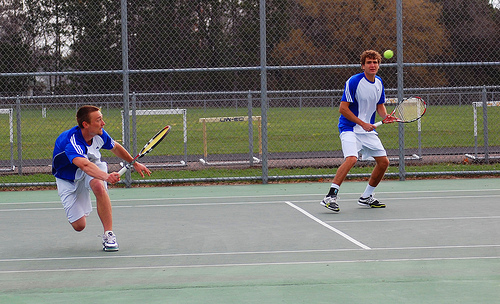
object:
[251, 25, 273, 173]
metal pole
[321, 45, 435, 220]
guy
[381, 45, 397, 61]
tennis ball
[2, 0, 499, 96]
fence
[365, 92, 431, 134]
racket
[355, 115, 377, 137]
hand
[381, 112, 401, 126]
hand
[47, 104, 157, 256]
guy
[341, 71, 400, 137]
shirt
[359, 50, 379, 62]
hair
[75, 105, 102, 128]
hair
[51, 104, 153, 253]
man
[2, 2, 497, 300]
air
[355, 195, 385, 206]
shoe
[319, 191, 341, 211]
shoe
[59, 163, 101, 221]
shorts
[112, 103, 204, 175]
racket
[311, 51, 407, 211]
man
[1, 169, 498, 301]
tennis court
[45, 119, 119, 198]
shirt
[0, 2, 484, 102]
forest